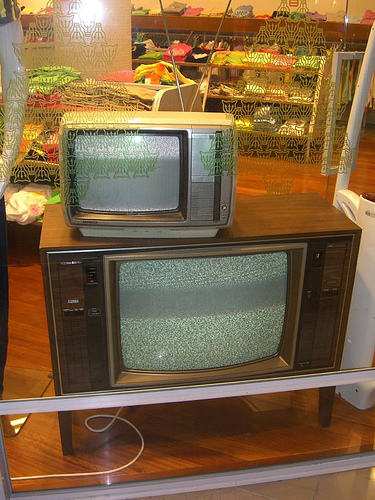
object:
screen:
[69, 132, 183, 222]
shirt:
[137, 50, 164, 60]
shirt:
[309, 9, 330, 20]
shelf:
[128, 12, 374, 157]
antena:
[199, 48, 219, 78]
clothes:
[61, 77, 161, 114]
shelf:
[0, 77, 205, 228]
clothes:
[23, 60, 83, 95]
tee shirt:
[164, 39, 191, 63]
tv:
[63, 108, 236, 242]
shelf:
[201, 40, 345, 163]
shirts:
[206, 45, 326, 151]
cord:
[7, 408, 143, 478]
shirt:
[165, 40, 190, 62]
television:
[43, 189, 364, 460]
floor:
[0, 150, 374, 488]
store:
[2, 3, 373, 498]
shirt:
[5, 185, 45, 227]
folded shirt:
[183, 44, 212, 62]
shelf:
[132, 57, 320, 75]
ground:
[2, 125, 374, 498]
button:
[222, 204, 228, 211]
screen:
[121, 254, 287, 367]